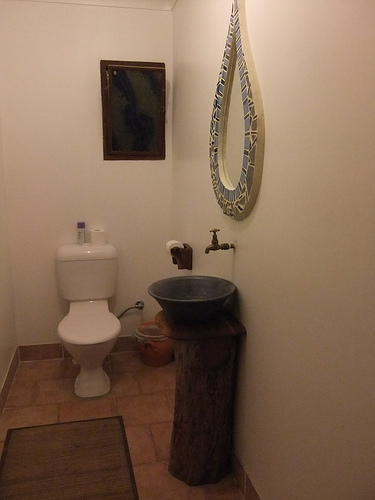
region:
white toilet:
[50, 243, 124, 399]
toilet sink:
[147, 268, 241, 493]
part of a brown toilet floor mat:
[2, 408, 143, 498]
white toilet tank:
[57, 242, 121, 306]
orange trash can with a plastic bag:
[130, 315, 170, 371]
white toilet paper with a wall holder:
[161, 232, 195, 275]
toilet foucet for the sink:
[199, 218, 237, 264]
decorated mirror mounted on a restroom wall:
[203, 0, 269, 226]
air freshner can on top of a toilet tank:
[69, 217, 87, 242]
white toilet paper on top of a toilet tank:
[89, 225, 108, 247]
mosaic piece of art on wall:
[206, 0, 268, 208]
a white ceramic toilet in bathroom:
[54, 247, 114, 397]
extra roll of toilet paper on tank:
[87, 224, 108, 249]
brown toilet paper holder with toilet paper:
[166, 238, 194, 271]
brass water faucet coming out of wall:
[201, 228, 246, 252]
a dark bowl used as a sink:
[150, 275, 242, 333]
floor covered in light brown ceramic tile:
[12, 348, 76, 422]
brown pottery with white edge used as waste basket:
[134, 315, 174, 367]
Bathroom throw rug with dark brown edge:
[5, 415, 132, 493]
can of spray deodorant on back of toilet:
[75, 221, 85, 246]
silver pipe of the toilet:
[119, 295, 147, 316]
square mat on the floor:
[2, 409, 145, 497]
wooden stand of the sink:
[167, 311, 247, 480]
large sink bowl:
[150, 265, 237, 316]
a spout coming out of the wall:
[200, 225, 238, 255]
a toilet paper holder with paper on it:
[165, 237, 191, 268]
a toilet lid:
[59, 307, 119, 346]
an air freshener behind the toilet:
[73, 221, 89, 243]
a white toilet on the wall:
[43, 221, 141, 395]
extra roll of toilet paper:
[85, 225, 111, 246]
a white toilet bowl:
[42, 225, 119, 407]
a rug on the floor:
[0, 398, 147, 489]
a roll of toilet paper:
[165, 230, 191, 272]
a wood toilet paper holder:
[172, 232, 195, 277]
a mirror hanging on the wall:
[192, 20, 263, 230]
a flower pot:
[126, 315, 170, 366]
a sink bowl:
[145, 259, 248, 314]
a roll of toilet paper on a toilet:
[87, 211, 111, 259]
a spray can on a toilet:
[73, 207, 90, 255]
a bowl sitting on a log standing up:
[160, 263, 242, 476]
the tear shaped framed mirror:
[207, 0, 264, 221]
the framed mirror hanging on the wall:
[209, 1, 265, 218]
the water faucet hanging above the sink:
[204, 227, 232, 254]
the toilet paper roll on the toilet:
[90, 227, 105, 246]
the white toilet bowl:
[55, 239, 120, 395]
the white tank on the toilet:
[56, 241, 118, 302]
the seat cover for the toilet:
[55, 310, 119, 345]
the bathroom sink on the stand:
[148, 273, 235, 324]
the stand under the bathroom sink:
[154, 308, 246, 485]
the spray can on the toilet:
[76, 220, 85, 245]